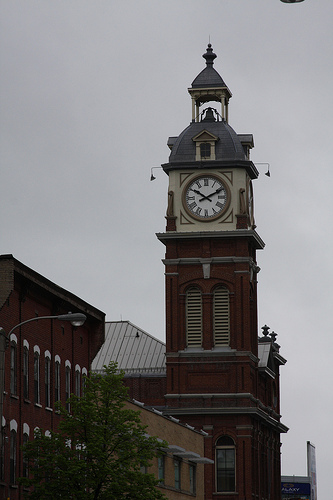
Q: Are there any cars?
A: No, there are no cars.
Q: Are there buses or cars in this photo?
A: No, there are no cars or buses.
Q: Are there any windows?
A: Yes, there is a window.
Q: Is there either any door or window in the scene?
A: Yes, there is a window.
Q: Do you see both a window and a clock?
A: Yes, there are both a window and a clock.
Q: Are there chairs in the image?
A: No, there are no chairs.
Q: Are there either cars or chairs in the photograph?
A: No, there are no chairs or cars.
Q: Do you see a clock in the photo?
A: Yes, there is a clock.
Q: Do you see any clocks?
A: Yes, there is a clock.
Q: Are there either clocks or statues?
A: Yes, there is a clock.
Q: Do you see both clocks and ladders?
A: No, there is a clock but no ladders.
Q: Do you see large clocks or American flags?
A: Yes, there is a large clock.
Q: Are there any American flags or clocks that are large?
A: Yes, the clock is large.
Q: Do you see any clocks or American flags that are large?
A: Yes, the clock is large.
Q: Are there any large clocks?
A: Yes, there is a large clock.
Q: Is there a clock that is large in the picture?
A: Yes, there is a large clock.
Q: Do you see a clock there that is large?
A: Yes, there is a clock that is large.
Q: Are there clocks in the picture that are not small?
A: Yes, there is a large clock.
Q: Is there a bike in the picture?
A: No, there are no bikes.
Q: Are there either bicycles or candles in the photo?
A: No, there are no bicycles or candles.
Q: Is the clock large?
A: Yes, the clock is large.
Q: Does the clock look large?
A: Yes, the clock is large.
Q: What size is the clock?
A: The clock is large.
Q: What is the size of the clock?
A: The clock is large.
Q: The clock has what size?
A: The clock is large.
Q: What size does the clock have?
A: The clock has large size.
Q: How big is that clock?
A: The clock is large.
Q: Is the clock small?
A: No, the clock is large.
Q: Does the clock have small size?
A: No, the clock is large.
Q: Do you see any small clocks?
A: No, there is a clock but it is large.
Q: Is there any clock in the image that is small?
A: No, there is a clock but it is large.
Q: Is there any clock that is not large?
A: No, there is a clock but it is large.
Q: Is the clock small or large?
A: The clock is large.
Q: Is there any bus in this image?
A: No, there are no buses.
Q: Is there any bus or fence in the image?
A: No, there are no buses or fences.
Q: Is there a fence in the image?
A: No, there are no fences.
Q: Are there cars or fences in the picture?
A: No, there are no fences or cars.